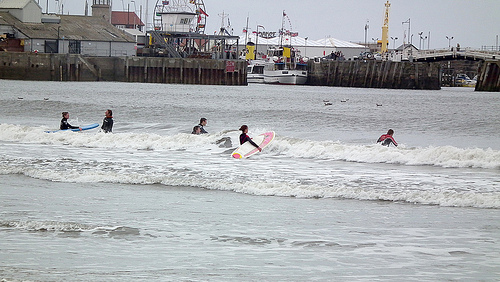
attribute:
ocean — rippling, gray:
[279, 140, 499, 280]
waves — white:
[106, 103, 473, 223]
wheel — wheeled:
[256, 133, 307, 163]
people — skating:
[55, 98, 404, 150]